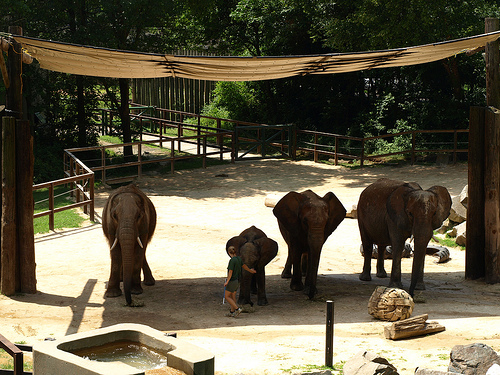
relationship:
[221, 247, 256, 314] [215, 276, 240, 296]
man has shirt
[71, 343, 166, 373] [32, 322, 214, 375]
water in container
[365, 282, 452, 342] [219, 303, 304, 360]
wood on floor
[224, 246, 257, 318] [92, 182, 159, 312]
man touching elephant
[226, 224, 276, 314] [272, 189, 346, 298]
elephant standing by elephant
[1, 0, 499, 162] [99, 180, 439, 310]
trees behind elephants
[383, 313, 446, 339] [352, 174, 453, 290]
log in front of elephant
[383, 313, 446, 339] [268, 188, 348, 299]
log in front of elephant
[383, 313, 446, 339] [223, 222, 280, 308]
log in front of elephant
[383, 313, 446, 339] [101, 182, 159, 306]
log in front of elephant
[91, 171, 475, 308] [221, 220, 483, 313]
elephants in shade of shade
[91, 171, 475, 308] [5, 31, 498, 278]
elephants in shade of canopy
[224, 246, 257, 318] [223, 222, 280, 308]
man touching elephant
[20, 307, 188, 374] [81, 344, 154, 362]
container filled with water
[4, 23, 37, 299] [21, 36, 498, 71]
pole/gathers along canopy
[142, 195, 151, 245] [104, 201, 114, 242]
ear behind ear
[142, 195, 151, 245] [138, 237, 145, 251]
ear behind tusk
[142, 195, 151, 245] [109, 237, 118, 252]
ear behind tusk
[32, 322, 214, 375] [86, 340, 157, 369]
container full of water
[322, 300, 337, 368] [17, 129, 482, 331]
pole in front of elephants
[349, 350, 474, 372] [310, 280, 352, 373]
rock next to pole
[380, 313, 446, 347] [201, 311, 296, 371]
log on ground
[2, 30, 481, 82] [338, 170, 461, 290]
canopy roof above elephants